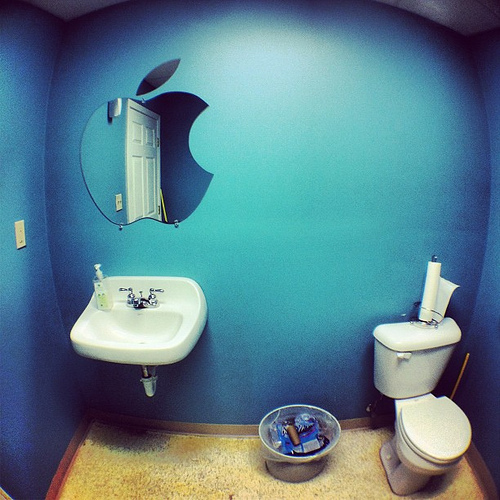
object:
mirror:
[78, 57, 214, 226]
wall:
[43, 1, 491, 435]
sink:
[69, 275, 209, 366]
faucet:
[117, 286, 164, 310]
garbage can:
[258, 403, 343, 485]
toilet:
[371, 316, 474, 497]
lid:
[399, 395, 473, 462]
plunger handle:
[449, 351, 472, 402]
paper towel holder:
[418, 255, 445, 325]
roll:
[419, 262, 461, 322]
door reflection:
[125, 98, 164, 225]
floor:
[57, 417, 488, 500]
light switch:
[115, 193, 123, 211]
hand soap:
[91, 262, 114, 313]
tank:
[371, 317, 463, 400]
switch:
[13, 219, 27, 249]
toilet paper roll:
[286, 425, 301, 446]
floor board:
[86, 405, 370, 437]